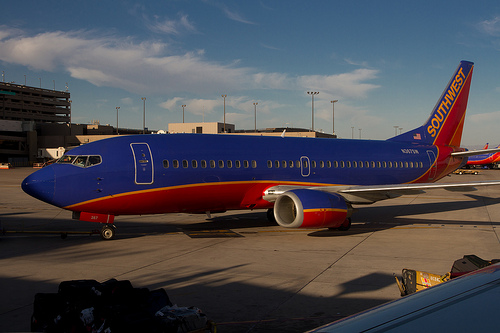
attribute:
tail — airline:
[432, 52, 478, 142]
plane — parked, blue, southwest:
[17, 101, 486, 213]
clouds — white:
[299, 44, 384, 121]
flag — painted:
[412, 128, 427, 144]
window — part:
[155, 147, 235, 167]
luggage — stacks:
[49, 261, 199, 332]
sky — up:
[64, 22, 421, 93]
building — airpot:
[128, 110, 303, 139]